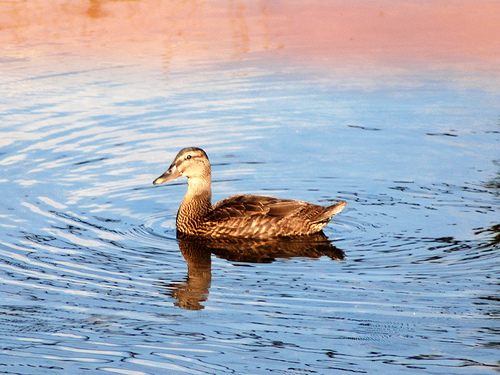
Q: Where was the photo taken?
A: It was taken at the pond.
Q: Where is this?
A: This is at the pond.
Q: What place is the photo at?
A: It is at the pond.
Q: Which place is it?
A: It is a pond.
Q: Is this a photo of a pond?
A: Yes, it is showing a pond.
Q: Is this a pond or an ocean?
A: It is a pond.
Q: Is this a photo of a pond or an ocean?
A: It is showing a pond.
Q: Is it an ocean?
A: No, it is a pond.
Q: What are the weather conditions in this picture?
A: It is sunny.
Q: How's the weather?
A: It is sunny.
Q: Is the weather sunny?
A: Yes, it is sunny.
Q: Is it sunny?
A: Yes, it is sunny.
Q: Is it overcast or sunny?
A: It is sunny.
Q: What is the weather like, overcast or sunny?
A: It is sunny.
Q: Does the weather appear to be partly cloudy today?
A: No, it is sunny.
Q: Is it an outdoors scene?
A: Yes, it is outdoors.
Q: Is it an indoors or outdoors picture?
A: It is outdoors.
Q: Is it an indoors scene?
A: No, it is outdoors.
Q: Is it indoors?
A: No, it is outdoors.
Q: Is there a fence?
A: No, there are no fences.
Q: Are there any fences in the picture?
A: No, there are no fences.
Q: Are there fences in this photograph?
A: No, there are no fences.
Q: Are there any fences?
A: No, there are no fences.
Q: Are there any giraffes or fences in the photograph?
A: No, there are no fences or giraffes.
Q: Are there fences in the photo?
A: No, there are no fences.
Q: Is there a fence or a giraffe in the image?
A: No, there are no fences or giraffes.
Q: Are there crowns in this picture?
A: No, there are no crowns.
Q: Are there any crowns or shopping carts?
A: No, there are no crowns or shopping carts.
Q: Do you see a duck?
A: Yes, there is a duck.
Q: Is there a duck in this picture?
A: Yes, there is a duck.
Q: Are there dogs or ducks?
A: Yes, there is a duck.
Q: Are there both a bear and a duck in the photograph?
A: No, there is a duck but no bears.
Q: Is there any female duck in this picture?
A: Yes, there is a female duck.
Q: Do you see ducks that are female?
A: Yes, there is a duck that is female.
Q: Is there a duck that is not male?
A: Yes, there is a female duck.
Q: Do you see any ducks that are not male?
A: Yes, there is a female duck.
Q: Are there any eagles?
A: No, there are no eagles.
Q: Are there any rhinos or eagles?
A: No, there are no eagles or rhinos.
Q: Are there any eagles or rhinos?
A: No, there are no eagles or rhinos.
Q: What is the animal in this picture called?
A: The animal is a duck.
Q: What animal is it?
A: The animal is a duck.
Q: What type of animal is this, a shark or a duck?
A: This is a duck.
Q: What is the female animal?
A: The animal is a duck.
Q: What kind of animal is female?
A: The animal is a duck.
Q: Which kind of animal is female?
A: The animal is a duck.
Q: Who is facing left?
A: The duck is facing left.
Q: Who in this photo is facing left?
A: The duck is facing left.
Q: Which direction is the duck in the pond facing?
A: The duck is facing left.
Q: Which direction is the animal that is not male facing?
A: The duck is facing left.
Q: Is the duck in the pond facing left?
A: Yes, the duck is facing left.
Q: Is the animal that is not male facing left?
A: Yes, the duck is facing left.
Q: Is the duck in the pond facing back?
A: No, the duck is facing left.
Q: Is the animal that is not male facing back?
A: No, the duck is facing left.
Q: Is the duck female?
A: Yes, the duck is female.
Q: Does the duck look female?
A: Yes, the duck is female.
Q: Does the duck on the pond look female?
A: Yes, the duck is female.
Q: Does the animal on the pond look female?
A: Yes, the duck is female.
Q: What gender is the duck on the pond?
A: The duck is female.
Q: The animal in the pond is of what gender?
A: The duck is female.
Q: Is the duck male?
A: No, the duck is female.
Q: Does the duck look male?
A: No, the duck is female.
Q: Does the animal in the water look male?
A: No, the duck is female.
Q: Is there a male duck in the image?
A: No, there is a duck but she is female.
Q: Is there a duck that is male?
A: No, there is a duck but she is female.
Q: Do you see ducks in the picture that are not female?
A: No, there is a duck but she is female.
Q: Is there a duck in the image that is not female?
A: No, there is a duck but she is female.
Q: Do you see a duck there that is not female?
A: No, there is a duck but she is female.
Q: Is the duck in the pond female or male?
A: The duck is female.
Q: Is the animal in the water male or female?
A: The duck is female.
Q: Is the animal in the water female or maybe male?
A: The duck is female.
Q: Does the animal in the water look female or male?
A: The duck is female.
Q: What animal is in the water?
A: The duck is in the water.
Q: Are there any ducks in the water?
A: Yes, there is a duck in the water.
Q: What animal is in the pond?
A: The animal is a duck.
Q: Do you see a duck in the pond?
A: Yes, there is a duck in the pond.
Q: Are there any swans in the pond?
A: No, there is a duck in the pond.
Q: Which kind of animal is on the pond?
A: The animal is a duck.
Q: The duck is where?
A: The duck is on the pond.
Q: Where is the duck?
A: The duck is on the pond.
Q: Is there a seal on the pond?
A: No, there is a duck on the pond.